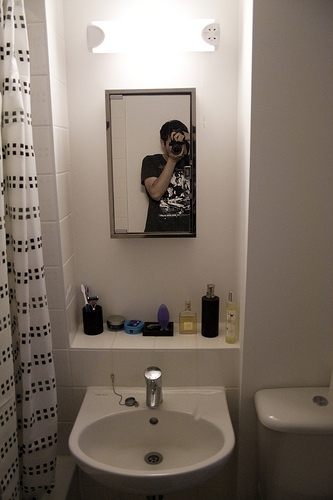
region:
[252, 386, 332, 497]
back part of toilet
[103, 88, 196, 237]
mirror with silver frame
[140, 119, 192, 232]
reflection of kid taking a selfie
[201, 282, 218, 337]
black tall perfume bottle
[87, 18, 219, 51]
light above mirror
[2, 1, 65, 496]
white with blak shower curtain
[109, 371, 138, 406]
sink plug on a chain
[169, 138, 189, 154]
reflection of black camera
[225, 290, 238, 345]
tall yellowtoiletry with flowers on label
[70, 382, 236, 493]
white bathroom sink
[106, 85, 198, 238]
a bathroom mirror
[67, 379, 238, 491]
a white sink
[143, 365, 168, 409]
a silver faucet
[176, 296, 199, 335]
a bottle of perfume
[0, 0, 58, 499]
a black and white shower curtain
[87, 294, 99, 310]
a shaver in a cup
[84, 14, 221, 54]
a light above mirror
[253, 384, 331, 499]
a white toilet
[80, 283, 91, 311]
tooth brushes in cup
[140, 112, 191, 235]
a reflection of man in mirror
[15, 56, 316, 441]
man taking a photo of himself in a bathroom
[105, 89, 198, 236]
man taking a photo of himself in a mirror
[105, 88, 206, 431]
man using a camera in a bathroom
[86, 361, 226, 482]
white bathroom sink with silver faucet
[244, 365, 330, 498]
white toilet bowel tank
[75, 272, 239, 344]
personal hygiene products for a man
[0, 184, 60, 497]
black and white geometric shower curtain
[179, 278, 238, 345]
cologne bottles on a bathroom shelf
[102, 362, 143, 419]
sink drain stopper on a chain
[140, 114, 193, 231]
man wearing a black and white t-shirt taking photos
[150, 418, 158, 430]
black hole is spotted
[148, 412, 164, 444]
black hole is spotted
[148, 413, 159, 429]
black hole is spotted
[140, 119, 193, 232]
The photographer reflected in a mirror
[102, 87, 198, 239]
a mirror hanging on a wall in a bathroom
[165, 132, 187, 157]
the photographer is holding a camera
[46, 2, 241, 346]
there is an alcove in the wall over the sink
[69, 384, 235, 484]
a white sink in a bathroom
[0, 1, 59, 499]
a white shower curtain with black squares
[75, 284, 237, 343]
grooming supplies sit in an alcove over the sink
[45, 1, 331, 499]
the wall of the bathroom is white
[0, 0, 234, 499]
the shower curtain hangs next to the sink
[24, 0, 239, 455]
white tile is on part of the walls